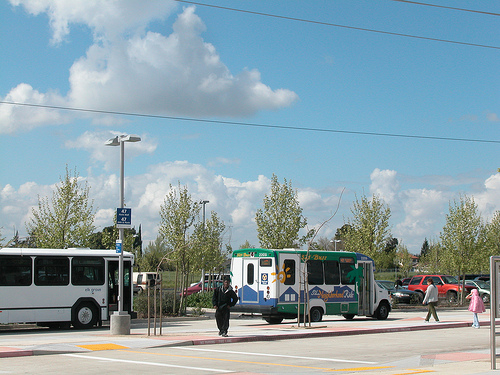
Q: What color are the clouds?
A: White.